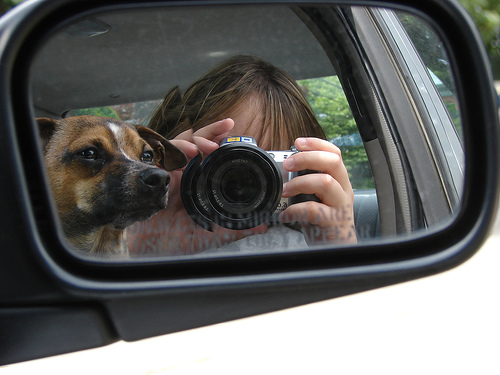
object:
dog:
[34, 115, 188, 258]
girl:
[140, 52, 359, 259]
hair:
[146, 58, 327, 150]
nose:
[140, 166, 174, 188]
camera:
[180, 136, 322, 233]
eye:
[141, 149, 154, 162]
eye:
[78, 148, 101, 160]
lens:
[181, 142, 283, 234]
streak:
[105, 121, 136, 162]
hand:
[134, 117, 267, 256]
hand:
[278, 136, 357, 247]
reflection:
[32, 3, 466, 262]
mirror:
[1, 0, 499, 367]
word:
[114, 195, 388, 259]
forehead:
[202, 91, 297, 150]